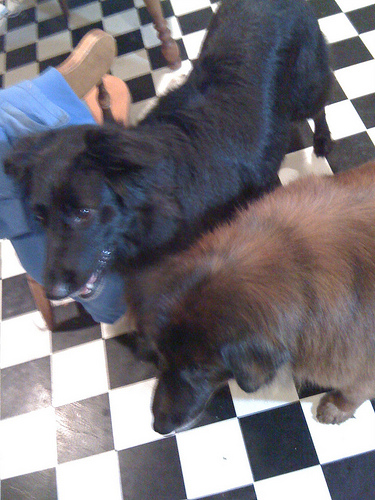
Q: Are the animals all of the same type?
A: Yes, all the animals are dogs.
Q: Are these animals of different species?
A: No, all the animals are dogs.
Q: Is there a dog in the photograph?
A: Yes, there are dogs.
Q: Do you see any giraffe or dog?
A: Yes, there are dogs.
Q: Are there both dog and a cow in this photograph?
A: No, there are dogs but no cows.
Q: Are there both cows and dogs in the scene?
A: No, there are dogs but no cows.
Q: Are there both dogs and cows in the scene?
A: No, there are dogs but no cows.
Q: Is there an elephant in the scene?
A: No, there are no elephants.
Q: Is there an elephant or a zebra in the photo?
A: No, there are no elephants or zebras.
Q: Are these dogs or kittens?
A: These are dogs.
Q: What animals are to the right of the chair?
A: The animals are dogs.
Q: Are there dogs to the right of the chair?
A: Yes, there are dogs to the right of the chair.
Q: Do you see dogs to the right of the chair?
A: Yes, there are dogs to the right of the chair.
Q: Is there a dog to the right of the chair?
A: Yes, there are dogs to the right of the chair.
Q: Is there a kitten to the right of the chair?
A: No, there are dogs to the right of the chair.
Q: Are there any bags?
A: No, there are no bags.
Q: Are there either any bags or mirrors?
A: No, there are no bags or mirrors.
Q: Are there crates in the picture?
A: No, there are no crates.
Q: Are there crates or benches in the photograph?
A: No, there are no crates or benches.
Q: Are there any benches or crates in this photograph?
A: No, there are no crates or benches.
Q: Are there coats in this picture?
A: Yes, there is a coat.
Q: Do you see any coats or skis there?
A: Yes, there is a coat.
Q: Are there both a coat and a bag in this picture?
A: No, there is a coat but no bags.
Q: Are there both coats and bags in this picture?
A: No, there is a coat but no bags.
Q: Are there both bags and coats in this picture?
A: No, there is a coat but no bags.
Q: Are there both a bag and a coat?
A: No, there is a coat but no bags.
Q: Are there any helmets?
A: No, there are no helmets.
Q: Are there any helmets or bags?
A: No, there are no helmets or bags.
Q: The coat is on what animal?
A: The coat is on the dog.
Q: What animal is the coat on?
A: The coat is on the dog.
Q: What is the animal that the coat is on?
A: The animal is a dog.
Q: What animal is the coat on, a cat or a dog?
A: The coat is on a dog.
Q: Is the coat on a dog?
A: Yes, the coat is on a dog.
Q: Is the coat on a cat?
A: No, the coat is on a dog.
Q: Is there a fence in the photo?
A: No, there are no fences.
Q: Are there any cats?
A: No, there are no cats.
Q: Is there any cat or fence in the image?
A: No, there are no cats or fences.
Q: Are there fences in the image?
A: No, there are no fences.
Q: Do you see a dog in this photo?
A: Yes, there is a dog.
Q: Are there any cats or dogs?
A: Yes, there is a dog.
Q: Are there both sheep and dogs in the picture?
A: No, there is a dog but no sheep.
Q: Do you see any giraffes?
A: No, there are no giraffes.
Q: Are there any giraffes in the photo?
A: No, there are no giraffes.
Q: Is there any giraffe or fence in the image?
A: No, there are no giraffes or fences.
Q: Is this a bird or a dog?
A: This is a dog.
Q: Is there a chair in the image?
A: Yes, there is a chair.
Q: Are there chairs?
A: Yes, there is a chair.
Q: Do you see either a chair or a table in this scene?
A: Yes, there is a chair.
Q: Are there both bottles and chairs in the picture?
A: No, there is a chair but no bottles.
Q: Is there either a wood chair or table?
A: Yes, there is a wood chair.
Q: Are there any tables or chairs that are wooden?
A: Yes, the chair is wooden.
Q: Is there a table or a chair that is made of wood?
A: Yes, the chair is made of wood.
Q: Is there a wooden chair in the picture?
A: Yes, there is a wood chair.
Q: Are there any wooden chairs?
A: Yes, there is a wood chair.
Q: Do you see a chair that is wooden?
A: Yes, there is a chair that is wooden.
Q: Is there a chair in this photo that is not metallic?
A: Yes, there is a wooden chair.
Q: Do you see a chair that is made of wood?
A: Yes, there is a chair that is made of wood.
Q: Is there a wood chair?
A: Yes, there is a chair that is made of wood.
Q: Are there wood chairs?
A: Yes, there is a chair that is made of wood.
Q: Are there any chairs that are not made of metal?
A: Yes, there is a chair that is made of wood.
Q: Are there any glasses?
A: No, there are no glasses.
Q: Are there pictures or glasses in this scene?
A: No, there are no glasses or pictures.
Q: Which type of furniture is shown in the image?
A: The furniture is a chair.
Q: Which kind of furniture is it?
A: The piece of furniture is a chair.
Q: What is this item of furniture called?
A: That is a chair.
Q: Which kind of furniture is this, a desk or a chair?
A: That is a chair.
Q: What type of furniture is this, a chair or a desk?
A: That is a chair.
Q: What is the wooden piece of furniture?
A: The piece of furniture is a chair.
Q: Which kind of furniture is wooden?
A: The furniture is a chair.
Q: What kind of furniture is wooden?
A: The furniture is a chair.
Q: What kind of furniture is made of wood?
A: The furniture is a chair.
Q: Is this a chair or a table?
A: This is a chair.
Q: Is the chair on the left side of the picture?
A: Yes, the chair is on the left of the image.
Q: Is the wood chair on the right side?
A: No, the chair is on the left of the image.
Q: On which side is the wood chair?
A: The chair is on the left of the image.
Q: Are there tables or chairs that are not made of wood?
A: No, there is a chair but it is made of wood.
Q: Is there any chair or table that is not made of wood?
A: No, there is a chair but it is made of wood.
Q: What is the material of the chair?
A: The chair is made of wood.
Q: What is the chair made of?
A: The chair is made of wood.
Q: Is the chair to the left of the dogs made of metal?
A: No, the chair is made of wood.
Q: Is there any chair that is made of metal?
A: No, there is a chair but it is made of wood.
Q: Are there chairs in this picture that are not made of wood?
A: No, there is a chair but it is made of wood.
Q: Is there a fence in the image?
A: No, there are no fences.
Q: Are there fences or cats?
A: No, there are no fences or cats.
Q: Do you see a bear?
A: No, there are no bears.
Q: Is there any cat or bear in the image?
A: No, there are no bears or cats.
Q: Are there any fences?
A: No, there are no fences.